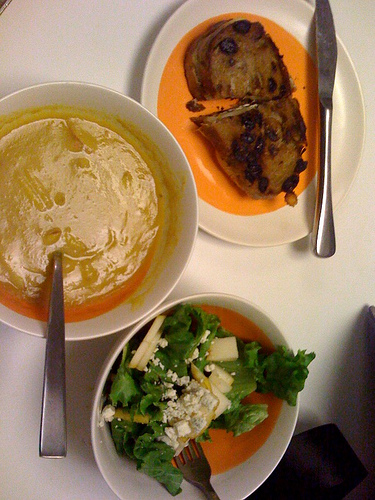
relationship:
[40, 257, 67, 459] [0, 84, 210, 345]
handle sticking out of bowl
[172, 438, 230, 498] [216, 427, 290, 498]
fork in white bowl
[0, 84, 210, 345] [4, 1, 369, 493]
bowl on table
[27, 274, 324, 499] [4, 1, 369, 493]
shadow on table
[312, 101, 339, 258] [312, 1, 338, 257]
handle of knife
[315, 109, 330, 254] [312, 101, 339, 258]
glare on handle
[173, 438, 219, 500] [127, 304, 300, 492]
fork in salad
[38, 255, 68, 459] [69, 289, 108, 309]
silver handle inside of orange liquid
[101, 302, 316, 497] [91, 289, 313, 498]
salad inside of white bowl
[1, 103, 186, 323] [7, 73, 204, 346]
soup inside of bowl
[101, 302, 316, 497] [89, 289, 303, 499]
salad inside of bowl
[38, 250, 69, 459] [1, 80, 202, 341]
spoon inside of soup bowl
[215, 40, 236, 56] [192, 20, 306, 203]
raisin inside of bread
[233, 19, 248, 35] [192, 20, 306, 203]
raisin inside of bread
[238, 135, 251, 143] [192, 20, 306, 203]
raisin inside of bread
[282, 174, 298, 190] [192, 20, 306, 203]
raisin inside of bread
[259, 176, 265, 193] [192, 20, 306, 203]
raisin inside of bread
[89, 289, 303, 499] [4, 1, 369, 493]
bowl sitting on table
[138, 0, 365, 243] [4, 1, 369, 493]
plate sitting on table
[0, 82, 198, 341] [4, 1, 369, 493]
bowl sitting on table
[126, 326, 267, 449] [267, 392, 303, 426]
salad inside of bowl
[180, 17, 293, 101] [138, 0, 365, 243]
bread on plate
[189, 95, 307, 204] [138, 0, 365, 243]
bread on plate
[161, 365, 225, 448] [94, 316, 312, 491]
cheese on salad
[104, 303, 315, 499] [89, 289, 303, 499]
lettuce in bowl